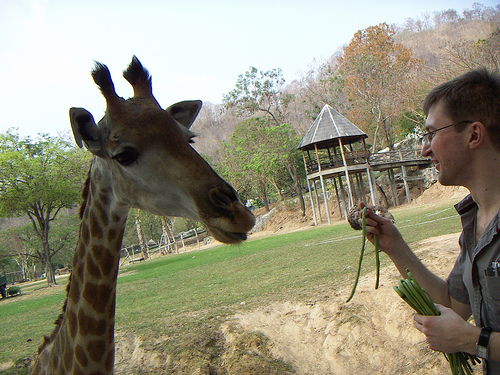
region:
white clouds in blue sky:
[4, 10, 47, 51]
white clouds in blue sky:
[14, 48, 61, 120]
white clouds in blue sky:
[150, 14, 208, 51]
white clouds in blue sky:
[230, 28, 300, 59]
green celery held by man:
[335, 190, 406, 292]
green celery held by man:
[383, 265, 462, 362]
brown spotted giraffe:
[63, 62, 255, 367]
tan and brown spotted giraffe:
[11, 45, 245, 346]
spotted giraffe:
[24, 60, 259, 367]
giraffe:
[7, 53, 231, 355]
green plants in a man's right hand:
[343, 198, 383, 304]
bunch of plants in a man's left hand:
[384, 261, 481, 373]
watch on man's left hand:
[473, 322, 498, 364]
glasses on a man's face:
[408, 116, 461, 144]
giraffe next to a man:
[9, 50, 275, 374]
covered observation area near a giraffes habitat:
[291, 96, 386, 233]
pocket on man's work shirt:
[480, 260, 499, 296]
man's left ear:
[458, 116, 486, 151]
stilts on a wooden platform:
[301, 161, 388, 223]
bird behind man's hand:
[333, 177, 398, 241]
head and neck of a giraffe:
[57, 57, 251, 372]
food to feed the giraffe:
[395, 272, 482, 371]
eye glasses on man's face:
[414, 124, 484, 140]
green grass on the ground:
[7, 215, 471, 349]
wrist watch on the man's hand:
[475, 325, 493, 362]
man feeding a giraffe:
[418, 66, 498, 369]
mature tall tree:
[0, 138, 82, 286]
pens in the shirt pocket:
[484, 259, 498, 276]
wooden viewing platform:
[300, 103, 375, 212]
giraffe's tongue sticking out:
[230, 229, 250, 242]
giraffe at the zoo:
[21, 33, 300, 331]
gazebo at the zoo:
[268, 83, 416, 238]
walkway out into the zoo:
[266, 96, 401, 211]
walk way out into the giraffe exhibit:
[291, 96, 421, 209]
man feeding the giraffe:
[43, 62, 493, 307]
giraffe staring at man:
[42, 41, 498, 251]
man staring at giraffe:
[37, 58, 498, 235]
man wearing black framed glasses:
[361, 60, 498, 251]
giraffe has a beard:
[165, 138, 282, 258]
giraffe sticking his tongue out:
[61, 59, 321, 282]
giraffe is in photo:
[71, 57, 252, 367]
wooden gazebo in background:
[300, 107, 380, 202]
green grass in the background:
[160, 264, 232, 287]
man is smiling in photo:
[420, 73, 497, 189]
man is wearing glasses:
[421, 126, 472, 145]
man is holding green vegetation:
[349, 204, 461, 368]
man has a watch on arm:
[473, 326, 494, 363]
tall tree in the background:
[2, 137, 63, 279]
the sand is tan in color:
[265, 316, 362, 359]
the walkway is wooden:
[370, 147, 432, 165]